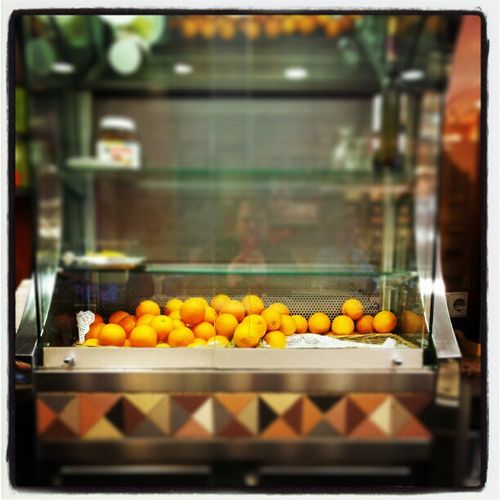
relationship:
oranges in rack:
[78, 286, 401, 346] [29, 285, 431, 370]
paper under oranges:
[76, 312, 405, 343] [78, 286, 401, 346]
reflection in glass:
[182, 186, 299, 300] [10, 13, 452, 363]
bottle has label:
[94, 113, 141, 164] [97, 138, 144, 170]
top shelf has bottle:
[62, 158, 413, 196] [94, 113, 144, 169]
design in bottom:
[40, 386, 435, 443] [19, 350, 463, 485]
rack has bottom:
[29, 285, 431, 370] [19, 350, 463, 485]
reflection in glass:
[84, 12, 372, 85] [52, 8, 391, 97]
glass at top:
[52, 8, 391, 97] [10, 21, 466, 119]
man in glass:
[182, 182, 305, 292] [10, 13, 452, 363]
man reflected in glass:
[182, 182, 305, 292] [10, 13, 452, 363]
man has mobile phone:
[182, 182, 305, 292] [240, 238, 263, 274]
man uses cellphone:
[182, 182, 305, 292] [240, 230, 265, 277]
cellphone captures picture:
[240, 230, 265, 277] [21, 13, 496, 468]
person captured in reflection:
[303, 207, 378, 285] [182, 186, 299, 300]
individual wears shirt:
[310, 201, 385, 297] [311, 247, 373, 292]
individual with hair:
[310, 201, 385, 297] [321, 201, 357, 243]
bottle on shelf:
[94, 113, 144, 169] [65, 165, 416, 193]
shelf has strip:
[35, 269, 427, 394] [38, 386, 432, 439]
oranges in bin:
[78, 286, 401, 346] [42, 276, 429, 366]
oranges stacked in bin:
[78, 286, 401, 346] [42, 276, 429, 366]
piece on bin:
[42, 341, 426, 370] [42, 276, 429, 366]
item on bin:
[38, 347, 419, 370] [42, 276, 429, 366]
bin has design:
[42, 276, 429, 366] [40, 386, 435, 443]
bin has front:
[42, 276, 429, 366] [35, 359, 447, 456]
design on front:
[40, 386, 435, 443] [35, 359, 447, 456]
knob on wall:
[449, 291, 467, 318] [432, 17, 481, 362]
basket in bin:
[64, 289, 388, 351] [42, 276, 429, 366]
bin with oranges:
[42, 276, 429, 366] [78, 286, 401, 346]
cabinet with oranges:
[8, 15, 486, 483] [78, 286, 401, 346]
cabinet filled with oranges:
[8, 15, 486, 483] [78, 286, 401, 346]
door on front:
[49, 439, 431, 489] [35, 359, 447, 456]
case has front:
[24, 17, 482, 468] [35, 359, 447, 456]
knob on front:
[390, 355, 411, 367] [35, 359, 447, 456]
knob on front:
[62, 352, 76, 365] [35, 359, 447, 456]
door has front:
[49, 439, 431, 489] [35, 359, 447, 456]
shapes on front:
[40, 386, 435, 443] [35, 359, 447, 456]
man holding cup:
[240, 236, 269, 275] [236, 237, 259, 286]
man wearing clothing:
[240, 236, 269, 275] [190, 241, 307, 296]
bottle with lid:
[94, 113, 144, 169] [102, 114, 140, 130]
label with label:
[97, 138, 144, 170] [95, 139, 143, 170]